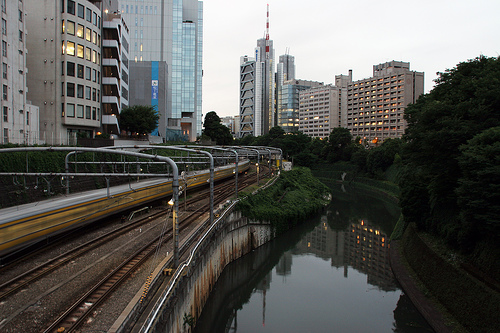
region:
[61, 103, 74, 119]
A window on the building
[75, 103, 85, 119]
A window on the building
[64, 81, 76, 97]
A window on the building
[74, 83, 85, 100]
A window on the building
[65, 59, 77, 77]
A window on the building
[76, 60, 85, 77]
A window on the building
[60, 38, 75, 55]
A window on the building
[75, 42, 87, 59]
A window on the building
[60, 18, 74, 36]
A window on the building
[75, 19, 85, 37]
A window on the building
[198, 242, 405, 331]
a man made river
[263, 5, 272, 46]
a beacon tower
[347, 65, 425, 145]
a building with lots of windows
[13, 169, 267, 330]
a set train of tracks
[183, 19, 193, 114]
some windows on the exterior of a building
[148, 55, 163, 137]
a banner hanging from a building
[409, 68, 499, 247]
a tree on the side of a river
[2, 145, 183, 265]
an overhang above the train tracks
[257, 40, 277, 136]
a skyscraper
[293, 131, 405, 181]
vegetation besides the river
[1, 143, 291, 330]
Train tracks covered by metal rails.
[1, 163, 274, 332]
Empty train tracks.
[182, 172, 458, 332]
A body of water.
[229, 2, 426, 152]
Buildings.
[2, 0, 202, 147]
Buildings on the edge of the tracks.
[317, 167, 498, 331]
Path by the water.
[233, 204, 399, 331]
Reflection of buildings in the water.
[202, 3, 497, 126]
Grey sky.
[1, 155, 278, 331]
Train tracks near the city.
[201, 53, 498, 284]
Green trees and bushes.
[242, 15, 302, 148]
a large building in the distance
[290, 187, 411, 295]
a reflection in the water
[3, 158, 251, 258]
a train going fast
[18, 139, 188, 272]
a overhang on train tracks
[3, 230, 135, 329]
train tracks with gravel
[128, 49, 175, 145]
a blue stripe on building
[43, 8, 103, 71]
lights shinning through windows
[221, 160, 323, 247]
a green growth beside the tracks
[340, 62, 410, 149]
a large building with lights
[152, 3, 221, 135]
a building with lots of windows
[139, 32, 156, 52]
window of tall building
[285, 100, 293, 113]
window of tall building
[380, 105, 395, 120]
window of tall building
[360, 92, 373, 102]
window of tall building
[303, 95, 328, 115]
window of tall building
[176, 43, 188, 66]
window of tall building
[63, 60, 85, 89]
window of tall building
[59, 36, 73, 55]
window of tall building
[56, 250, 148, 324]
set of train tracks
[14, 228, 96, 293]
set of train tracks